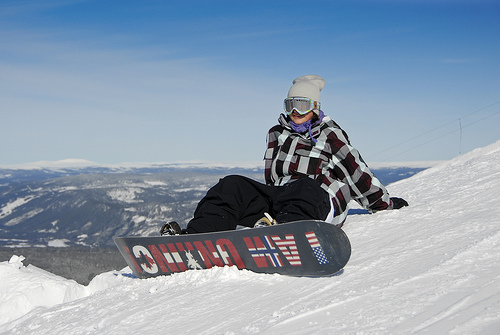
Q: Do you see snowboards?
A: Yes, there is a snowboard.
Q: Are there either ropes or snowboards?
A: Yes, there is a snowboard.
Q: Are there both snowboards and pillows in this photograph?
A: No, there is a snowboard but no pillows.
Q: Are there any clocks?
A: No, there are no clocks.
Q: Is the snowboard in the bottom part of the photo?
A: Yes, the snowboard is in the bottom of the image.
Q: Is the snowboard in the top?
A: No, the snowboard is in the bottom of the image.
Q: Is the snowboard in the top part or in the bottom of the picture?
A: The snowboard is in the bottom of the image.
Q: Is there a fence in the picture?
A: No, there are no fences.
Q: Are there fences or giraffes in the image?
A: No, there are no fences or giraffes.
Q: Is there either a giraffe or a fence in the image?
A: No, there are no fences or giraffes.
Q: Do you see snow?
A: Yes, there is snow.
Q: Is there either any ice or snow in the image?
A: Yes, there is snow.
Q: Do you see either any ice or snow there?
A: Yes, there is snow.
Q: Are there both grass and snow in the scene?
A: No, there is snow but no grass.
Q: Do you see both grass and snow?
A: No, there is snow but no grass.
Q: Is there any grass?
A: No, there is no grass.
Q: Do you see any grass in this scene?
A: No, there is no grass.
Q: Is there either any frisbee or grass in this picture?
A: No, there are no grass or frisbees.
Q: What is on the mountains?
A: The snow is on the mountains.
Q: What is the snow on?
A: The snow is on the mountains.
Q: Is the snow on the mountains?
A: Yes, the snow is on the mountains.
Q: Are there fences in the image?
A: No, there are no fences.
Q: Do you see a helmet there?
A: No, there are no helmets.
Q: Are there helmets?
A: No, there are no helmets.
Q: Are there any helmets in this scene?
A: No, there are no helmets.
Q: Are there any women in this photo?
A: Yes, there is a woman.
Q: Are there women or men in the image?
A: Yes, there is a woman.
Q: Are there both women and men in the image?
A: No, there is a woman but no men.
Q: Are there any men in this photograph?
A: No, there are no men.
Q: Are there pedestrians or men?
A: No, there are no men or pedestrians.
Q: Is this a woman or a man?
A: This is a woman.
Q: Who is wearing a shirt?
A: The woman is wearing a shirt.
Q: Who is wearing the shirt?
A: The woman is wearing a shirt.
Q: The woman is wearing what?
A: The woman is wearing a shirt.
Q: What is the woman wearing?
A: The woman is wearing a shirt.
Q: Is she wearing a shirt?
A: Yes, the woman is wearing a shirt.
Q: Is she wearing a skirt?
A: No, the woman is wearing a shirt.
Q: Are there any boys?
A: No, there are no boys.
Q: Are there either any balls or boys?
A: No, there are no boys or balls.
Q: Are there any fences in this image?
A: No, there are no fences.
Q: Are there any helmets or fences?
A: No, there are no fences or helmets.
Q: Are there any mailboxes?
A: No, there are no mailboxes.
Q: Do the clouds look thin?
A: Yes, the clouds are thin.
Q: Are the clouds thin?
A: Yes, the clouds are thin.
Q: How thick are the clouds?
A: The clouds are thin.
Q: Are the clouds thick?
A: No, the clouds are thin.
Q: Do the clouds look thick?
A: No, the clouds are thin.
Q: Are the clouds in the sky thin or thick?
A: The clouds are thin.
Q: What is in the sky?
A: The clouds are in the sky.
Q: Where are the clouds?
A: The clouds are in the sky.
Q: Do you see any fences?
A: No, there are no fences.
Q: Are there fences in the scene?
A: No, there are no fences.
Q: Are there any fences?
A: No, there are no fences.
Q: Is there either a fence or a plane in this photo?
A: No, there are no fences or airplanes.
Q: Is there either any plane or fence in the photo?
A: No, there are no fences or airplanes.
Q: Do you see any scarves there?
A: Yes, there is a scarf.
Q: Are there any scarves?
A: Yes, there is a scarf.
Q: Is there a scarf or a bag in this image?
A: Yes, there is a scarf.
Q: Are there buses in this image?
A: No, there are no buses.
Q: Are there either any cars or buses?
A: No, there are no buses or cars.